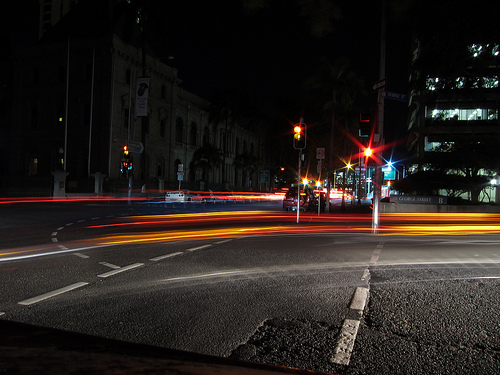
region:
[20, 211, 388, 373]
white dotted lines on the street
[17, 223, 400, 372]
lines painted on the road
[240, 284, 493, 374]
patchy pavement in the street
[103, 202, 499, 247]
yellow blur of lights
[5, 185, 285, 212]
red blue of lights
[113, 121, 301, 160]
traffic lights on either side of the street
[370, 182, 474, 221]
sidewalk in front of building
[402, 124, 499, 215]
trees on the right side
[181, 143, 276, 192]
trees in front on building on the left side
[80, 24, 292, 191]
building on the left side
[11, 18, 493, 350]
a night slow motion shot of traffic moving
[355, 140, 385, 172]
the traffic signal light is red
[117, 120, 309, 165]
traffic signal lights are red and orange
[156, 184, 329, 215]
cars are parked on both sides of the road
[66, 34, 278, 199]
the building's lights are out in the front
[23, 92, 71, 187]
lights are on the side of the building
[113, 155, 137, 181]
the pedestrian traffic signals are red and green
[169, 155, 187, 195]
signs are on the side of the road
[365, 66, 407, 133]
directional signs are on a pole at the intersection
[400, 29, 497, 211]
lights are on in the office building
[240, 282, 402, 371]
A marked tarmac road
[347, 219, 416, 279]
A marked tarmac road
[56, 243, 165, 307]
A marked tarmac road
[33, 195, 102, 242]
A marked tarmac road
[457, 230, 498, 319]
A marked tarmac road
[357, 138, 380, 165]
Bright lit street light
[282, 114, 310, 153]
Bright lit street light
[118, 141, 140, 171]
Bright lit street light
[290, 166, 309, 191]
Bright lit street light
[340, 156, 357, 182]
Bright lit street light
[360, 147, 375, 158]
red colored traffic light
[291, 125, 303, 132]
red colored traffic light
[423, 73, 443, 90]
glass window on building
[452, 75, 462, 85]
glass window on building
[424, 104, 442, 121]
glass window on building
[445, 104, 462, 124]
glass window on building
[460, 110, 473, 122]
glass window on building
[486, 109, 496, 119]
glass window on building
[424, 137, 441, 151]
glass window on building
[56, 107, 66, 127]
glass window on building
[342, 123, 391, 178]
shiny red star burst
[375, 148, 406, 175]
shiny blue star burst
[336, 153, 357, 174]
shiny yellow star burst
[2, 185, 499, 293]
long exposure light trails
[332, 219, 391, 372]
white lines painted across the street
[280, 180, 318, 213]
parked red SUV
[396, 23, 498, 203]
multi story office building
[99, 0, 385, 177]
dark black night sky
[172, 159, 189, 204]
shadowy street sign and pole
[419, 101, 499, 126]
row of windows illuminated by fluorescent tubing